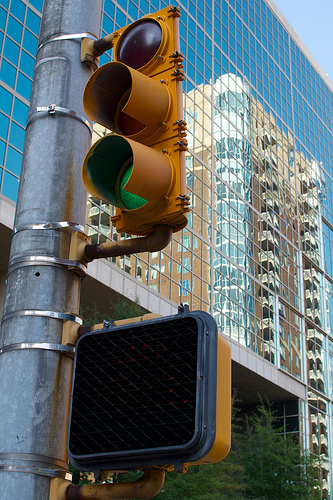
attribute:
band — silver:
[20, 299, 82, 340]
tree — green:
[69, 293, 328, 498]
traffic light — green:
[80, 5, 189, 233]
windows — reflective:
[194, 57, 330, 316]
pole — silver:
[2, 3, 104, 499]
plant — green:
[245, 396, 331, 487]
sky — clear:
[279, 0, 332, 47]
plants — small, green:
[252, 408, 281, 488]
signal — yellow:
[80, 25, 182, 237]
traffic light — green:
[81, 133, 174, 213]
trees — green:
[174, 400, 324, 499]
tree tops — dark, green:
[123, 383, 323, 498]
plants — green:
[290, 445, 328, 498]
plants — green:
[257, 397, 292, 497]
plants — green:
[206, 386, 242, 496]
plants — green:
[166, 472, 203, 499]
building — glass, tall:
[0, 0, 332, 499]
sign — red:
[74, 318, 234, 460]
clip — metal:
[1, 308, 85, 323]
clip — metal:
[4, 255, 88, 274]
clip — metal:
[0, 464, 72, 480]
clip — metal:
[22, 105, 92, 136]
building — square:
[182, 21, 277, 167]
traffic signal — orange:
[62, 4, 192, 282]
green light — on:
[78, 132, 173, 232]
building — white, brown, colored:
[236, 14, 324, 100]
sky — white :
[273, 1, 331, 85]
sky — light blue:
[276, 2, 331, 66]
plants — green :
[226, 379, 326, 494]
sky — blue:
[266, 0, 332, 91]